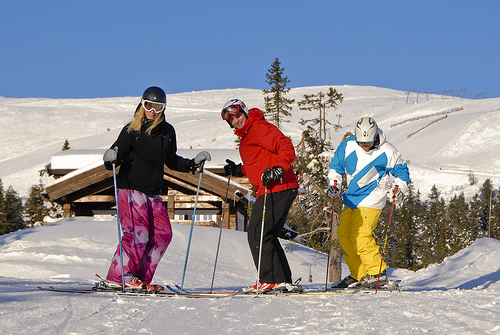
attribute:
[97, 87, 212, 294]
skier — female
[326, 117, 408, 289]
skier — female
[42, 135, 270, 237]
house — small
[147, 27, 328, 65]
clouds — white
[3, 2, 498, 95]
sky — blue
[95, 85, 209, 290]
woman skier — near land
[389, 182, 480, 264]
trees — pine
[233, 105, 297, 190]
jacket — red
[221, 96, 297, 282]
skier — female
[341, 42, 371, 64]
clouds — white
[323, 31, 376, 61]
clouds — white